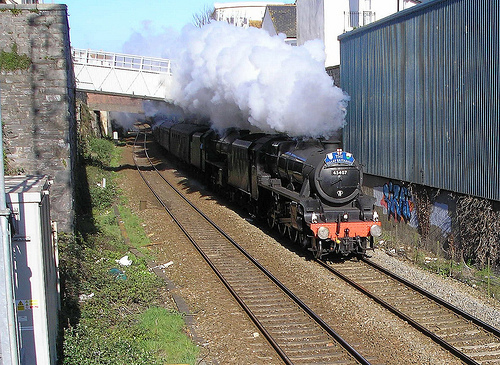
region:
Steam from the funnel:
[118, 17, 355, 137]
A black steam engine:
[249, 126, 396, 264]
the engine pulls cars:
[146, 115, 263, 216]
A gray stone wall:
[1, 5, 84, 232]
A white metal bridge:
[64, 40, 239, 101]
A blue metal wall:
[331, 16, 498, 178]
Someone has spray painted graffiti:
[373, 180, 451, 250]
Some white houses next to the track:
[253, 0, 405, 76]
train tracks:
[211, 268, 487, 363]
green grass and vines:
[68, 215, 201, 363]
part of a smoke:
[291, 72, 338, 112]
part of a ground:
[212, 309, 249, 339]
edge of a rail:
[226, 292, 270, 330]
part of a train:
[304, 110, 396, 269]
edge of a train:
[278, 165, 312, 234]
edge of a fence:
[375, 122, 442, 203]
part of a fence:
[425, 118, 478, 189]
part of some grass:
[101, 310, 138, 348]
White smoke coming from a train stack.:
[122, 21, 347, 141]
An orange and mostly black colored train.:
[150, 111, 385, 259]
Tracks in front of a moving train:
[314, 242, 497, 364]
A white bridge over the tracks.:
[68, 46, 180, 100]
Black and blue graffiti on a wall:
[380, 178, 415, 224]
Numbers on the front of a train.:
[330, 167, 347, 177]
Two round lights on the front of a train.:
[317, 226, 382, 238]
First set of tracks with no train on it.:
[132, 127, 368, 364]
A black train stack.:
[320, 127, 344, 147]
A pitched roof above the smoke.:
[260, 4, 297, 39]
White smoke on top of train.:
[186, 38, 326, 134]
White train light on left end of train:
[312, 223, 339, 242]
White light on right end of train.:
[363, 225, 392, 245]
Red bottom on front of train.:
[306, 218, 388, 239]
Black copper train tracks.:
[181, 223, 280, 306]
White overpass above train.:
[76, 50, 181, 101]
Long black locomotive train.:
[146, 106, 388, 266]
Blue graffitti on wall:
[383, 184, 425, 228]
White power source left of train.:
[10, 170, 86, 362]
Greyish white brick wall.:
[31, 41, 87, 169]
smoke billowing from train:
[128, 2, 375, 262]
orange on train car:
[275, 130, 407, 296]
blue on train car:
[301, 135, 403, 216]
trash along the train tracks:
[98, 176, 229, 362]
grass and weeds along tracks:
[99, 179, 192, 291]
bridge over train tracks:
[64, 27, 247, 135]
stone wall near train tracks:
[17, 5, 192, 215]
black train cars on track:
[164, 97, 375, 258]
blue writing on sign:
[367, 180, 439, 238]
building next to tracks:
[325, 21, 480, 287]